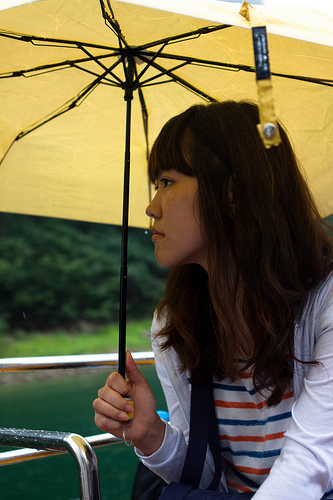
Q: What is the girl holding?
A: An umbrella.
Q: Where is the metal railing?
A: Behind the girl.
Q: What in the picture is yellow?
A: The umbrella.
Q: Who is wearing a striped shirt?
A: The girl.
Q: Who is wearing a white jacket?
A: The girl.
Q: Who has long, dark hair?
A: The girl.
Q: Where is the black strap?
A: Over the girl's shoulder.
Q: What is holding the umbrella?
A: The girl's hand.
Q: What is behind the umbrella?
A: Trees.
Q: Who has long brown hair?
A: The woman.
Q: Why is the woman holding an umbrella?
A: It is raining.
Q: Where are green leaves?
A: On the trees.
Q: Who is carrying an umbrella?
A: The woman.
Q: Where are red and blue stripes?
A: On a shirt.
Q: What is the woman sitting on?
A: A boat.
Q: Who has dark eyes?
A: The lady.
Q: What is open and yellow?
A: Umbrella.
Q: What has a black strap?
A: The bag.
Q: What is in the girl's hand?
A: Umbrella handle.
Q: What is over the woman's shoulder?
A: A strap.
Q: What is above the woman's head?
A: Umbrella.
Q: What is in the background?
A: Green trees.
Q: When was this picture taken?
A: Daytime.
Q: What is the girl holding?
A: An umbrella.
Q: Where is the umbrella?
A: Over her head.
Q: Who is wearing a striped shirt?
A: The girl.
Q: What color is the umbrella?
A: Yellow.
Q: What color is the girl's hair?
A: Black.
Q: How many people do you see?
A: 1.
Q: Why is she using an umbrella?
A: Keep her dry.